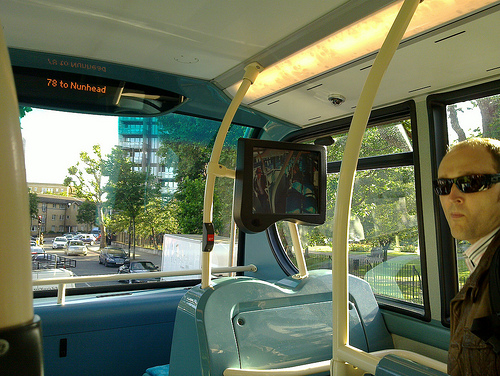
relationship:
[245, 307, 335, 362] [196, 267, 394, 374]
reflection on seat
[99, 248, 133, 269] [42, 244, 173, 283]
car parked on street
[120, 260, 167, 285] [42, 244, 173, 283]
car parked on street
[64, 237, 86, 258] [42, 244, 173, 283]
car parked on street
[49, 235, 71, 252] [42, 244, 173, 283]
car parked on street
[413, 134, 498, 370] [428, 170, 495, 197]
man wearing sunglasses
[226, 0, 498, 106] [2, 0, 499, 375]
light in bus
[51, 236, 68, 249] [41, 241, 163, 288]
car on street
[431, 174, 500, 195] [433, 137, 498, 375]
glasses on man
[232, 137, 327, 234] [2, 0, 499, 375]
telivision on bus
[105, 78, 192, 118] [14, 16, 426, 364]
mirror on bus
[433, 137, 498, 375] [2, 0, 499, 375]
man on bus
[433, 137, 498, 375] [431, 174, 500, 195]
man wearing glasses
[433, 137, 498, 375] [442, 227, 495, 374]
man wearing jacket